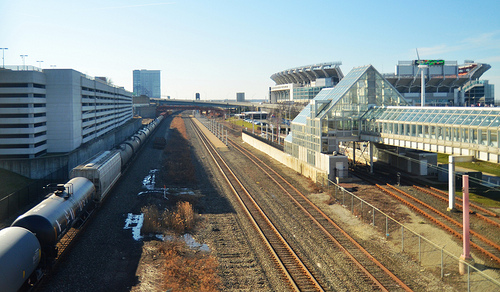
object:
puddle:
[123, 210, 145, 241]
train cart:
[10, 176, 95, 268]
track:
[185, 116, 329, 292]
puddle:
[152, 231, 211, 254]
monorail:
[360, 104, 500, 164]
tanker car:
[0, 225, 45, 291]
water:
[158, 234, 213, 254]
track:
[201, 117, 418, 291]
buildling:
[131, 68, 162, 99]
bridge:
[151, 98, 262, 117]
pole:
[459, 173, 477, 257]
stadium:
[269, 57, 493, 107]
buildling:
[281, 62, 439, 177]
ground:
[0, 113, 500, 291]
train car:
[111, 142, 134, 169]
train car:
[124, 136, 143, 156]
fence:
[323, 177, 500, 292]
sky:
[1, 2, 499, 101]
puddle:
[168, 184, 192, 191]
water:
[135, 191, 148, 196]